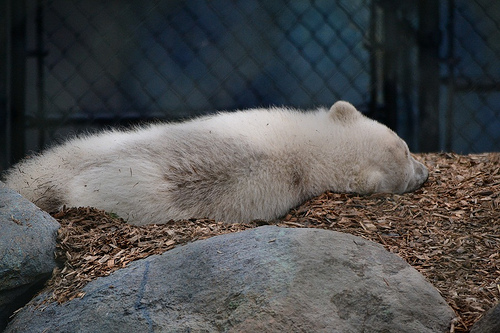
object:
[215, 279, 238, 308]
part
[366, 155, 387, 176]
part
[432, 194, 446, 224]
part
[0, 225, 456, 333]
rock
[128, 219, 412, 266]
edge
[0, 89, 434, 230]
dog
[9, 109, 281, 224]
back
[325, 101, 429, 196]
head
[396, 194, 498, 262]
surface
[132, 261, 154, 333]
mark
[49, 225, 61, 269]
gap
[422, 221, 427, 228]
chips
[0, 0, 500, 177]
fence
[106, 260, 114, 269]
chips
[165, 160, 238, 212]
gray spot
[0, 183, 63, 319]
boulder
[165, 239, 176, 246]
woodchips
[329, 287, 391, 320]
spot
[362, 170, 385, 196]
ear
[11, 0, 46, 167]
pole